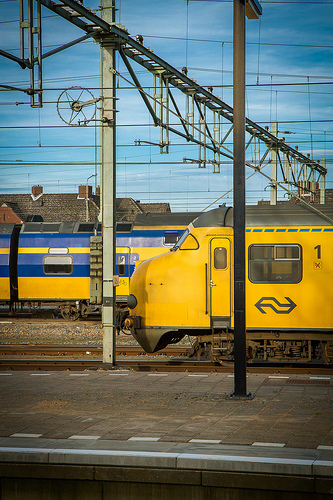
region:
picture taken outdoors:
[8, 21, 302, 450]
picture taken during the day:
[50, 94, 307, 393]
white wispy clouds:
[34, 73, 172, 139]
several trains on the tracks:
[19, 218, 323, 360]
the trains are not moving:
[15, 222, 322, 387]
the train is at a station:
[134, 202, 331, 383]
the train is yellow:
[183, 239, 225, 317]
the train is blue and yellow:
[14, 236, 101, 296]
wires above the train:
[137, 59, 285, 164]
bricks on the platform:
[115, 371, 190, 428]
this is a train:
[125, 205, 332, 351]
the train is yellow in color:
[157, 256, 195, 321]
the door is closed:
[208, 235, 229, 323]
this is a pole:
[230, 237, 250, 406]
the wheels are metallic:
[269, 331, 312, 366]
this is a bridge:
[165, 74, 208, 125]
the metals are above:
[158, 88, 216, 143]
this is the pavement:
[96, 381, 197, 433]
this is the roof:
[49, 195, 80, 218]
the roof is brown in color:
[43, 195, 74, 214]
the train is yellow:
[120, 219, 225, 361]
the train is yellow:
[178, 201, 331, 370]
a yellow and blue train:
[23, 208, 106, 319]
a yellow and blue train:
[10, 203, 194, 390]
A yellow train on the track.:
[138, 211, 323, 338]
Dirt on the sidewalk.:
[38, 382, 209, 421]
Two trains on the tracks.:
[39, 227, 322, 361]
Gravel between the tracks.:
[8, 310, 102, 350]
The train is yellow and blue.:
[24, 218, 137, 309]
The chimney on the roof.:
[59, 165, 99, 202]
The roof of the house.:
[14, 189, 138, 228]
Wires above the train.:
[123, 90, 319, 201]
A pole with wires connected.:
[212, 3, 265, 377]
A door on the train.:
[201, 232, 231, 337]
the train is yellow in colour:
[155, 254, 233, 321]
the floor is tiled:
[112, 398, 234, 428]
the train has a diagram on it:
[256, 296, 295, 318]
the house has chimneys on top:
[21, 180, 91, 205]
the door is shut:
[204, 237, 227, 313]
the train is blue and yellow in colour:
[4, 236, 90, 278]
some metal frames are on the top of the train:
[139, 45, 227, 169]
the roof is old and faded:
[39, 204, 78, 216]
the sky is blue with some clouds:
[122, 163, 169, 189]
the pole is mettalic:
[231, 308, 246, 386]